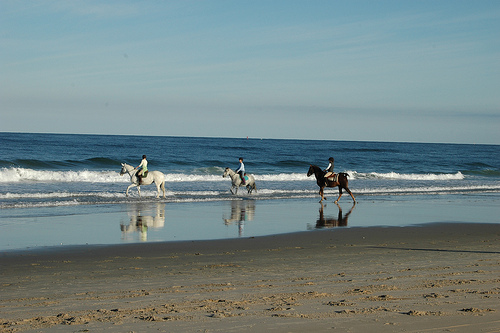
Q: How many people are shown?
A: 3.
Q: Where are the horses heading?
A: Toward water.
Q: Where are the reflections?
A: On water.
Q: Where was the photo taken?
A: Beach.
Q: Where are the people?
A: Horseback.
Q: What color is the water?
A: Blue.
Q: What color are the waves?
A: White.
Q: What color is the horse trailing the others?
A: Brown.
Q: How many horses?
A: 3.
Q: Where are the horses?
A: On beach.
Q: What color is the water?
A: Blue.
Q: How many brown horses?
A: 1.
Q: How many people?
A: 3.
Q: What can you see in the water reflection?
A: Horses and riders.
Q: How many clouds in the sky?
A: None.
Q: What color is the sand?
A: Brown.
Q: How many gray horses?
A: 1.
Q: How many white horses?
A: 1.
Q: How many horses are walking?
A: 3.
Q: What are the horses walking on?
A: Sand.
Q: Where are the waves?
A: Water.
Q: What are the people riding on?
A: Horses.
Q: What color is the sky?
A: Blue.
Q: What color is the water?
A: Blue.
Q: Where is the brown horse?
A: On the right.